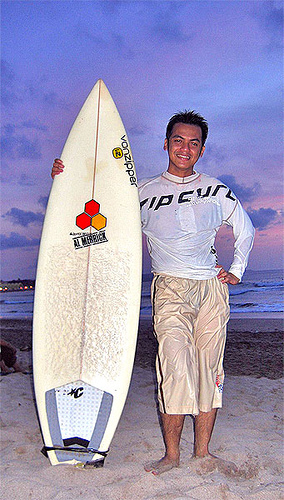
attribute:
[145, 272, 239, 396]
shorts — beige, black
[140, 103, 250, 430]
man — young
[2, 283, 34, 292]
lights — red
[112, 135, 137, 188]
logo — small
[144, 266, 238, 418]
shorts — pair of, wet, surf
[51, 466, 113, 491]
sand — white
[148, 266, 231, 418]
shorts — tan, white, long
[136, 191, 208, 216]
logo — large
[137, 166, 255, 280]
shirt — white, long sleeve, surfing 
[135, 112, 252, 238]
man — looking directly at camera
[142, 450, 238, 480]
feet — bare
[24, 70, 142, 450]
surfboard — long, white and red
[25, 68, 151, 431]
surfboard — beige, grey, yellow, black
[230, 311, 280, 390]
beach — during a sunset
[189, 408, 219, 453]
leg — hairy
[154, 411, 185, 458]
leg — hairy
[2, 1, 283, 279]
sky — pink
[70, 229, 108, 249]
text — Al Merrick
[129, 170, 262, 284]
shirt — white, black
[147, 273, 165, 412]
stripe — black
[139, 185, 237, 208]
text — RIP CURL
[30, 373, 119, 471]
surfboard rudder — top side of